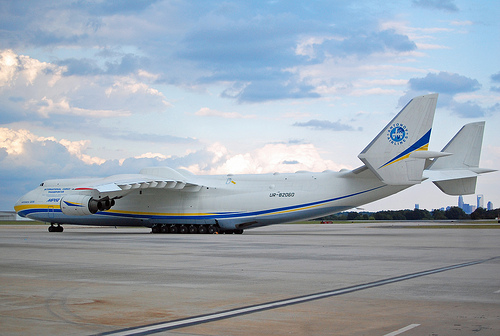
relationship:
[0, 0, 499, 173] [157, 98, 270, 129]
cloud in sky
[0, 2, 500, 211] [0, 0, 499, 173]
sky in cloud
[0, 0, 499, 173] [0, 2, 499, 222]
cloud in sky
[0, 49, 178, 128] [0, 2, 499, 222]
cloud in sky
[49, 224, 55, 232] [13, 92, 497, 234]
wheel in front of airplane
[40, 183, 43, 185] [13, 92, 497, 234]
window of airplane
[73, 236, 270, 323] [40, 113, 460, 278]
roadway used by airplane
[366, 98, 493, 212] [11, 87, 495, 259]
tail of airplane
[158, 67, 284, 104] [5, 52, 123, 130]
sky with no clouds